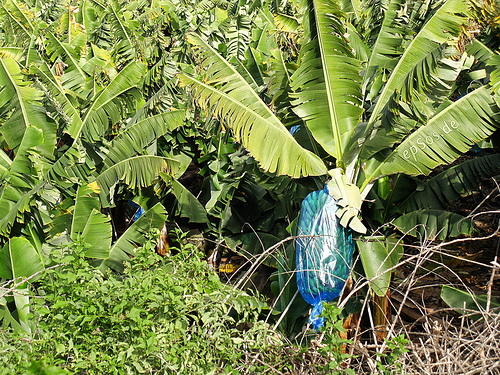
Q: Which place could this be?
A: It is a field.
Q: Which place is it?
A: It is a field.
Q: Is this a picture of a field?
A: Yes, it is showing a field.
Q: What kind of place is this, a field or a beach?
A: It is a field.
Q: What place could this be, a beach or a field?
A: It is a field.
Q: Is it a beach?
A: No, it is a field.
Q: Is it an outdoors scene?
A: Yes, it is outdoors.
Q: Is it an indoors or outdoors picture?
A: It is outdoors.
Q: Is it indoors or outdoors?
A: It is outdoors.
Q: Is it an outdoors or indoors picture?
A: It is outdoors.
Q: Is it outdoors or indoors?
A: It is outdoors.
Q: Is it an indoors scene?
A: No, it is outdoors.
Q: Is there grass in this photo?
A: Yes, there is grass.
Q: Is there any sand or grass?
A: Yes, there is grass.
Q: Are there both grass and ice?
A: No, there is grass but no ice.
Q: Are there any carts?
A: No, there are no carts.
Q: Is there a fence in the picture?
A: No, there are no fences.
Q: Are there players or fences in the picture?
A: No, there are no fences or players.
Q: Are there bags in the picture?
A: Yes, there is a bag.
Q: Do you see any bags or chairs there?
A: Yes, there is a bag.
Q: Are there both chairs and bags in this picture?
A: No, there is a bag but no chairs.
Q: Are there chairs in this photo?
A: No, there are no chairs.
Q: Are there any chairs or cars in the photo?
A: No, there are no chairs or cars.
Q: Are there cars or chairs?
A: No, there are no chairs or cars.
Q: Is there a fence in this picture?
A: No, there are no fences.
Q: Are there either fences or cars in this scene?
A: No, there are no fences or cars.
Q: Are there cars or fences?
A: No, there are no fences or cars.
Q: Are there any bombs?
A: No, there are no bombs.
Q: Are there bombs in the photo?
A: No, there are no bombs.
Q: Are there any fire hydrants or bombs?
A: No, there are no bombs or fire hydrants.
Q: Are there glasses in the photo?
A: No, there are no glasses.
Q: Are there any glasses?
A: No, there are no glasses.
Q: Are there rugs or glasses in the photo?
A: No, there are no glasses or rugs.